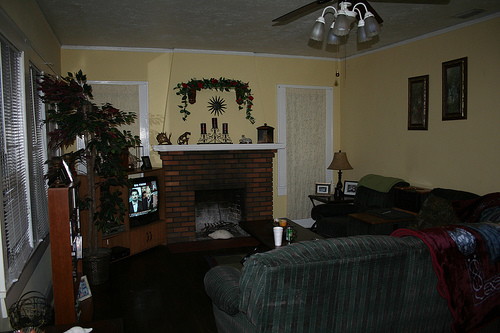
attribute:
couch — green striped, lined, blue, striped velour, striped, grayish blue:
[203, 186, 499, 332]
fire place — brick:
[153, 143, 287, 244]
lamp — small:
[328, 149, 354, 199]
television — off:
[128, 175, 161, 228]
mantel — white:
[156, 143, 284, 152]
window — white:
[0, 9, 60, 293]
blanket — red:
[390, 220, 499, 332]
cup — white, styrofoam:
[273, 225, 284, 246]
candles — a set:
[197, 117, 234, 144]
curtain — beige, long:
[286, 87, 327, 220]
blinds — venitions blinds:
[1, 37, 55, 284]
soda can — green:
[286, 226, 292, 242]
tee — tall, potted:
[36, 69, 144, 286]